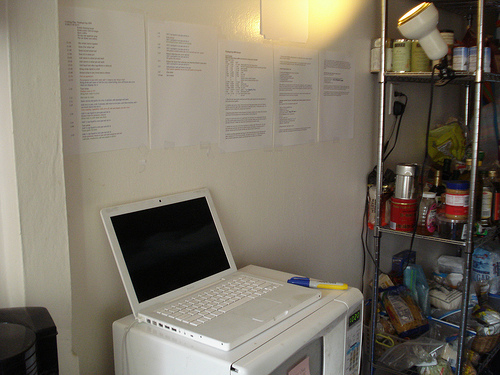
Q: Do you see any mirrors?
A: No, there are no mirrors.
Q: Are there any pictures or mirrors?
A: No, there are no mirrors or pictures.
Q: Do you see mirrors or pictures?
A: No, there are no mirrors or pictures.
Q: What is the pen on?
A: The pen is on the microwave.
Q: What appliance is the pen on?
A: The pen is on the microwave.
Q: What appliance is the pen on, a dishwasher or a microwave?
A: The pen is on a microwave.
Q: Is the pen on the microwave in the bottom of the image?
A: Yes, the pen is on the microwave.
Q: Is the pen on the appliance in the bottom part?
A: Yes, the pen is on the microwave.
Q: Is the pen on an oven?
A: No, the pen is on the microwave.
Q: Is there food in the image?
A: Yes, there is food.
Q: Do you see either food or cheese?
A: Yes, there is food.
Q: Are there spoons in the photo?
A: No, there are no spoons.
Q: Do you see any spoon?
A: No, there are no spoons.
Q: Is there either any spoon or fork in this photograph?
A: No, there are no spoons or forks.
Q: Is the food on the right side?
A: Yes, the food is on the right of the image.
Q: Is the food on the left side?
A: No, the food is on the right of the image.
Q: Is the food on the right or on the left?
A: The food is on the right of the image.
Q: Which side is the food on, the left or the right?
A: The food is on the right of the image.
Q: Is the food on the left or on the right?
A: The food is on the right of the image.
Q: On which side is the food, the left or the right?
A: The food is on the right of the image.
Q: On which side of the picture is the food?
A: The food is on the right of the image.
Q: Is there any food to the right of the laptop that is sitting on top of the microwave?
A: Yes, there is food to the right of the laptop.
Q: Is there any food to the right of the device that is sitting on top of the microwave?
A: Yes, there is food to the right of the laptop.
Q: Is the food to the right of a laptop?
A: Yes, the food is to the right of a laptop.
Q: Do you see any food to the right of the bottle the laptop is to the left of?
A: Yes, there is food to the right of the bottle.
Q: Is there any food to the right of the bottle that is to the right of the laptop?
A: Yes, there is food to the right of the bottle.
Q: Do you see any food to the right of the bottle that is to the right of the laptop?
A: Yes, there is food to the right of the bottle.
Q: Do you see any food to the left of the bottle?
A: No, the food is to the right of the bottle.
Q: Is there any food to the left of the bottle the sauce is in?
A: No, the food is to the right of the bottle.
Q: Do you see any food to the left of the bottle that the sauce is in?
A: No, the food is to the right of the bottle.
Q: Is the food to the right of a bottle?
A: Yes, the food is to the right of a bottle.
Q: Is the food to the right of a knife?
A: No, the food is to the right of a bottle.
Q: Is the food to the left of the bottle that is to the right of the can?
A: No, the food is to the right of the bottle.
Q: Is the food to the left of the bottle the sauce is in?
A: No, the food is to the right of the bottle.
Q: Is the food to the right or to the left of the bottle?
A: The food is to the right of the bottle.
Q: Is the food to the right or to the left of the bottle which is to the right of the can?
A: The food is to the right of the bottle.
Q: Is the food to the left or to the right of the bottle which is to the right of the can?
A: The food is to the right of the bottle.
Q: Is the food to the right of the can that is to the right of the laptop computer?
A: Yes, the food is to the right of the can.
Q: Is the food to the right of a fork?
A: No, the food is to the right of the can.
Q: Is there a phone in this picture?
A: No, there are no phones.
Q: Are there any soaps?
A: No, there are no soaps.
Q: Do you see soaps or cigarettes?
A: No, there are no soaps or cigarettes.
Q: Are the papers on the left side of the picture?
A: Yes, the papers are on the left of the image.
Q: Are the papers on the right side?
A: No, the papers are on the left of the image.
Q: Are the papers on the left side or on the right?
A: The papers are on the left of the image.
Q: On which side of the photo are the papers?
A: The papers are on the left of the image.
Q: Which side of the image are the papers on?
A: The papers are on the left of the image.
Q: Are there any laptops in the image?
A: Yes, there is a laptop.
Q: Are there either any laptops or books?
A: Yes, there is a laptop.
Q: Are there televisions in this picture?
A: No, there are no televisions.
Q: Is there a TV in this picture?
A: No, there are no televisions.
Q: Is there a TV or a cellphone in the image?
A: No, there are no televisions or cell phones.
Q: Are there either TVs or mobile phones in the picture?
A: No, there are no TVs or mobile phones.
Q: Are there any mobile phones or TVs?
A: No, there are no TVs or mobile phones.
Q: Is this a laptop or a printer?
A: This is a laptop.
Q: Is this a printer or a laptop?
A: This is a laptop.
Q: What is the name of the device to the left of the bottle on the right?
A: The device is a laptop.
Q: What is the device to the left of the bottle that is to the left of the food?
A: The device is a laptop.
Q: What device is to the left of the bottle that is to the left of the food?
A: The device is a laptop.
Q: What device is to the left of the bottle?
A: The device is a laptop.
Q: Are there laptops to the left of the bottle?
A: Yes, there is a laptop to the left of the bottle.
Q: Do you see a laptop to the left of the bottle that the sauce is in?
A: Yes, there is a laptop to the left of the bottle.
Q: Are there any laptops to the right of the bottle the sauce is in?
A: No, the laptop is to the left of the bottle.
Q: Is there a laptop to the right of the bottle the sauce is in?
A: No, the laptop is to the left of the bottle.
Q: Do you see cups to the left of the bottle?
A: No, there is a laptop to the left of the bottle.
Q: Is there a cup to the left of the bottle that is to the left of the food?
A: No, there is a laptop to the left of the bottle.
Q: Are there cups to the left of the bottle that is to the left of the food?
A: No, there is a laptop to the left of the bottle.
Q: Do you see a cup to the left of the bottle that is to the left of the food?
A: No, there is a laptop to the left of the bottle.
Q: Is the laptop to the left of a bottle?
A: Yes, the laptop is to the left of a bottle.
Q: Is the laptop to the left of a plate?
A: No, the laptop is to the left of a bottle.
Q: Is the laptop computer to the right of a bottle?
A: No, the laptop computer is to the left of a bottle.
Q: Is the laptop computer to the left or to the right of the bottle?
A: The laptop computer is to the left of the bottle.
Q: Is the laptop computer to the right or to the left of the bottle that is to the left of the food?
A: The laptop computer is to the left of the bottle.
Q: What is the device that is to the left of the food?
A: The device is a laptop.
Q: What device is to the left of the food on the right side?
A: The device is a laptop.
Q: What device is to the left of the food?
A: The device is a laptop.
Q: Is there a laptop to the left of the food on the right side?
A: Yes, there is a laptop to the left of the food.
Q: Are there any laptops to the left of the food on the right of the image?
A: Yes, there is a laptop to the left of the food.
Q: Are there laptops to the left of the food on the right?
A: Yes, there is a laptop to the left of the food.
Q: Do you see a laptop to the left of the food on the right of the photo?
A: Yes, there is a laptop to the left of the food.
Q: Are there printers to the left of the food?
A: No, there is a laptop to the left of the food.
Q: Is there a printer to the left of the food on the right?
A: No, there is a laptop to the left of the food.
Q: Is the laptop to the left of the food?
A: Yes, the laptop is to the left of the food.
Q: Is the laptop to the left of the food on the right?
A: Yes, the laptop is to the left of the food.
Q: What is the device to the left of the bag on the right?
A: The device is a laptop.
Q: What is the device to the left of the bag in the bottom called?
A: The device is a laptop.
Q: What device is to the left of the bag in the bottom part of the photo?
A: The device is a laptop.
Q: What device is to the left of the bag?
A: The device is a laptop.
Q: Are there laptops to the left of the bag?
A: Yes, there is a laptop to the left of the bag.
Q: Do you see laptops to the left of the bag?
A: Yes, there is a laptop to the left of the bag.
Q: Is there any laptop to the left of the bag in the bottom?
A: Yes, there is a laptop to the left of the bag.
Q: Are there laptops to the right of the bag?
A: No, the laptop is to the left of the bag.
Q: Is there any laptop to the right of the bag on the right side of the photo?
A: No, the laptop is to the left of the bag.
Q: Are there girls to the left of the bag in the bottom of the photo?
A: No, there is a laptop to the left of the bag.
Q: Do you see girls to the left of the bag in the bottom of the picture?
A: No, there is a laptop to the left of the bag.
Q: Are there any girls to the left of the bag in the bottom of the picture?
A: No, there is a laptop to the left of the bag.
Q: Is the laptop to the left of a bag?
A: Yes, the laptop is to the left of a bag.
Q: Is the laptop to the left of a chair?
A: No, the laptop is to the left of a bag.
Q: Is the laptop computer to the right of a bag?
A: No, the laptop computer is to the left of a bag.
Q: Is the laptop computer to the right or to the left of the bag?
A: The laptop computer is to the left of the bag.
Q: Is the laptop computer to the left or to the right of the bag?
A: The laptop computer is to the left of the bag.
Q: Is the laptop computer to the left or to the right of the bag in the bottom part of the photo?
A: The laptop computer is to the left of the bag.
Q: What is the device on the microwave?
A: The device is a laptop.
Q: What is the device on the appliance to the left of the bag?
A: The device is a laptop.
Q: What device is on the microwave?
A: The device is a laptop.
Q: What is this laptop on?
A: The laptop is on the microwave.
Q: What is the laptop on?
A: The laptop is on the microwave.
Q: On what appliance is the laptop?
A: The laptop is on the microwave.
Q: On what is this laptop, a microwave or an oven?
A: The laptop is on a microwave.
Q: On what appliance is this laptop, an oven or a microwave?
A: The laptop is on a microwave.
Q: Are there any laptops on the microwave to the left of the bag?
A: Yes, there is a laptop on the microwave.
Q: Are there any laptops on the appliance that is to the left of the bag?
A: Yes, there is a laptop on the microwave.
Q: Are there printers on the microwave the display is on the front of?
A: No, there is a laptop on the microwave.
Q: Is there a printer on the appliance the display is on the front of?
A: No, there is a laptop on the microwave.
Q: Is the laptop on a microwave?
A: Yes, the laptop is on a microwave.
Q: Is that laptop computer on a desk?
A: No, the laptop computer is on a microwave.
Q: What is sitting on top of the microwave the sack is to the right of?
A: The laptop is sitting on top of the microwave.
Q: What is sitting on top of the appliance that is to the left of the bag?
A: The laptop is sitting on top of the microwave.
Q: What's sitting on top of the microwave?
A: The laptop is sitting on top of the microwave.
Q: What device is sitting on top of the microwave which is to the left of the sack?
A: The device is a laptop.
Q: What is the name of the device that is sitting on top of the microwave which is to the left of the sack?
A: The device is a laptop.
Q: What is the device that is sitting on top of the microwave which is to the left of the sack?
A: The device is a laptop.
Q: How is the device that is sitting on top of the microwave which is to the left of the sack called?
A: The device is a laptop.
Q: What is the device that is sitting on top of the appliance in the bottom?
A: The device is a laptop.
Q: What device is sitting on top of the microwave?
A: The device is a laptop.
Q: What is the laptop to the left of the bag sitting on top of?
A: The laptop is sitting on top of the microwave.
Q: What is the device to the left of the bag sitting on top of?
A: The laptop is sitting on top of the microwave.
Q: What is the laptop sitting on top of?
A: The laptop is sitting on top of the microwave.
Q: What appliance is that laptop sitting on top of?
A: The laptop is sitting on top of the microwave.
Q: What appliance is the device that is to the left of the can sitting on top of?
A: The laptop is sitting on top of the microwave.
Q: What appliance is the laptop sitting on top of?
A: The laptop is sitting on top of the microwave.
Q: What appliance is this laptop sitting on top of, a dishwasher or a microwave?
A: The laptop is sitting on top of a microwave.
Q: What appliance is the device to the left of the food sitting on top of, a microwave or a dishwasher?
A: The laptop is sitting on top of a microwave.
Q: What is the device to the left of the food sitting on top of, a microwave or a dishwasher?
A: The laptop is sitting on top of a microwave.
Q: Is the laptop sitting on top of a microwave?
A: Yes, the laptop is sitting on top of a microwave.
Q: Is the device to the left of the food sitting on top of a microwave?
A: Yes, the laptop is sitting on top of a microwave.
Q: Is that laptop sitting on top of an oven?
A: No, the laptop is sitting on top of a microwave.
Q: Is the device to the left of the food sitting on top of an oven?
A: No, the laptop is sitting on top of a microwave.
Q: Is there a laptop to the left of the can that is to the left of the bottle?
A: Yes, there is a laptop to the left of the can.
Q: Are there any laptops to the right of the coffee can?
A: No, the laptop is to the left of the can.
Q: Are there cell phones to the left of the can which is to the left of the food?
A: No, there is a laptop to the left of the can.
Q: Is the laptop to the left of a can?
A: Yes, the laptop is to the left of a can.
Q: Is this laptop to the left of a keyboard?
A: No, the laptop is to the left of a can.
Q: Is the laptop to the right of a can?
A: No, the laptop is to the left of a can.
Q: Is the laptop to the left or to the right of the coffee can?
A: The laptop is to the left of the can.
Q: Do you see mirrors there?
A: No, there are no mirrors.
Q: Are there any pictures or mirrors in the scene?
A: No, there are no mirrors or pictures.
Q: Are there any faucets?
A: No, there are no faucets.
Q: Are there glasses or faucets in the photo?
A: No, there are no faucets or glasses.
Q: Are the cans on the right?
A: Yes, the cans are on the right of the image.